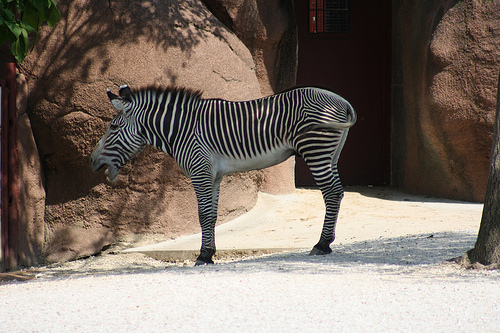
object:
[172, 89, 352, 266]
body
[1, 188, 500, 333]
ground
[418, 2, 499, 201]
rock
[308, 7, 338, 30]
window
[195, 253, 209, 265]
hooves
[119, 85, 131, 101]
ears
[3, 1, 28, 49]
leaves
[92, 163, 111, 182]
mouth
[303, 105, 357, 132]
tail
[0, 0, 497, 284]
pen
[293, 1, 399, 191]
doorway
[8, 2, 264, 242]
wall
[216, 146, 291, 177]
underbelly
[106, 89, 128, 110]
ear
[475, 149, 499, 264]
tree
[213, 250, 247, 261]
grate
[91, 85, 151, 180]
head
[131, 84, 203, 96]
mane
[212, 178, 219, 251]
legs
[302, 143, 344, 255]
hind legs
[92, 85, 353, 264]
zebra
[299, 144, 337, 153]
stripes